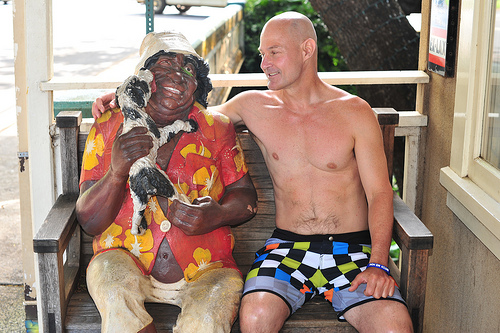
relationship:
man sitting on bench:
[209, 10, 412, 332] [32, 109, 432, 331]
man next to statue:
[209, 10, 412, 332] [73, 30, 258, 332]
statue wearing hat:
[73, 30, 258, 332] [136, 28, 202, 71]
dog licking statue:
[117, 66, 211, 236] [73, 30, 258, 332]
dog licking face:
[117, 66, 211, 236] [149, 53, 199, 110]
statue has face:
[73, 30, 258, 332] [149, 53, 199, 110]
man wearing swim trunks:
[209, 10, 412, 332] [244, 224, 406, 313]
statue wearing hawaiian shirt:
[73, 30, 258, 332] [81, 105, 246, 279]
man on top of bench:
[209, 10, 412, 332] [32, 109, 432, 331]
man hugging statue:
[209, 10, 412, 332] [73, 30, 258, 332]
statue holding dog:
[73, 30, 258, 332] [117, 66, 211, 236]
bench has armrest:
[32, 109, 432, 331] [32, 191, 77, 252]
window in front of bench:
[441, 3, 500, 257] [32, 109, 432, 331]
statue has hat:
[73, 30, 258, 332] [136, 28, 202, 71]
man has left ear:
[209, 10, 412, 332] [301, 37, 316, 58]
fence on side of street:
[173, 7, 257, 91] [0, 1, 219, 332]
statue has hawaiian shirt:
[73, 30, 258, 332] [81, 105, 246, 279]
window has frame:
[441, 3, 500, 257] [453, 17, 472, 177]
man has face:
[209, 10, 412, 332] [259, 30, 297, 85]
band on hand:
[366, 261, 388, 272] [348, 266, 395, 299]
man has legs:
[209, 10, 412, 332] [239, 284, 412, 332]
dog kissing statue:
[117, 66, 211, 236] [73, 30, 258, 332]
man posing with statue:
[209, 10, 412, 332] [73, 30, 258, 332]